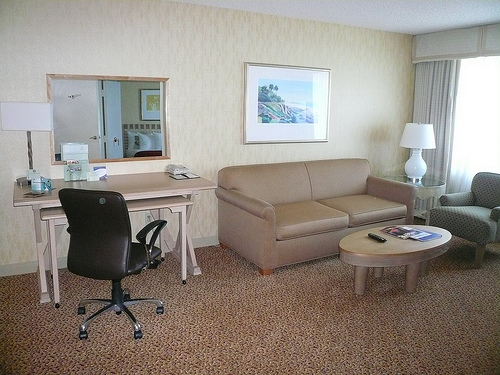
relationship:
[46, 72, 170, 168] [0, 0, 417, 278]
mirror in wall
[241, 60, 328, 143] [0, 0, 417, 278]
artwork in wall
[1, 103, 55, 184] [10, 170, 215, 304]
lamp in desk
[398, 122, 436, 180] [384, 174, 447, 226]
lamp in table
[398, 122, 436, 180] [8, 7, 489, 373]
lamp in room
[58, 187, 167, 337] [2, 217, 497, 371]
chair in floor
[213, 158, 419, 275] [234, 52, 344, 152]
leather couch in picture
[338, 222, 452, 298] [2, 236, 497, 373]
table in floor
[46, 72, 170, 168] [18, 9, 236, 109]
mirror in wall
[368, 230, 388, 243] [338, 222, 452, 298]
remote in table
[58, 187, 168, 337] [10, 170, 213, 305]
chair in desk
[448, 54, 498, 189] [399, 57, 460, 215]
window with curtain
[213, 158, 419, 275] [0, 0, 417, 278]
leather couch against wall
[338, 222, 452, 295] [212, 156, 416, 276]
table in front of sofa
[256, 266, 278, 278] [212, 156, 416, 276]
leg on sofa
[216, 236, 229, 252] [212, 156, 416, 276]
leg on sofa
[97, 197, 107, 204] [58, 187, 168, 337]
circle on back of chair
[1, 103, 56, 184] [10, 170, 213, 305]
lamp on desk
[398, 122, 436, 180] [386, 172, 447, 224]
lamp on table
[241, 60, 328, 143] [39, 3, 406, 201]
artwork on wall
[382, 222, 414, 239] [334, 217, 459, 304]
books on top of table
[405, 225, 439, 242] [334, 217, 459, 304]
books on top of table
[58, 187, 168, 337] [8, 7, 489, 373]
chair in room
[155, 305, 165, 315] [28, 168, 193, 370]
black wheel on chair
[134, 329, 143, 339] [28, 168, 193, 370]
black wheel on chair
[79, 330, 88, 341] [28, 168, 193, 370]
black wheel on chair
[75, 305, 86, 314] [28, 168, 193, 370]
black wheel on chair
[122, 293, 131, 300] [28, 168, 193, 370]
black wheel on chair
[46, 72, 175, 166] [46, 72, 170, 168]
framed on mirror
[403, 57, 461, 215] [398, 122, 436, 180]
curtain behind lamp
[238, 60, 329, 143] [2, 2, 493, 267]
artwork on wall